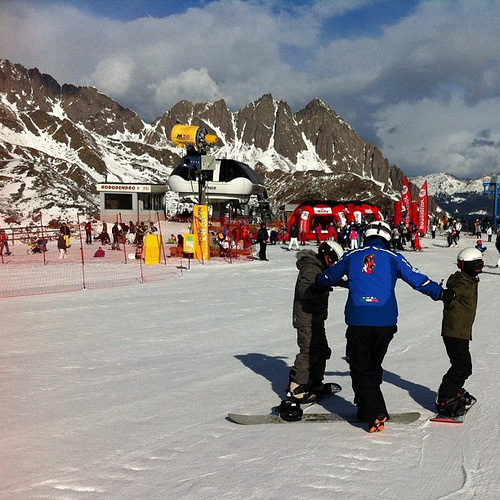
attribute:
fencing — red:
[1, 216, 259, 296]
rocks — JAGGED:
[149, 85, 441, 183]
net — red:
[0, 228, 259, 299]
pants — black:
[345, 323, 395, 425]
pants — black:
[440, 333, 474, 398]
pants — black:
[289, 325, 334, 388]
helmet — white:
[364, 221, 396, 243]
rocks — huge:
[193, 99, 407, 180]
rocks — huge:
[8, 62, 160, 142]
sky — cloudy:
[72, 1, 494, 138]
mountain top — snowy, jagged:
[294, 90, 345, 130]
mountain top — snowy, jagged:
[240, 87, 295, 130]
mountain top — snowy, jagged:
[172, 95, 232, 121]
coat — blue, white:
[344, 239, 404, 339]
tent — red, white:
[276, 196, 391, 247]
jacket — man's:
[331, 250, 435, 320]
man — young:
[276, 235, 337, 423]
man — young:
[328, 204, 431, 431]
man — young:
[434, 238, 485, 426]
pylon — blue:
[477, 78, 485, 232]